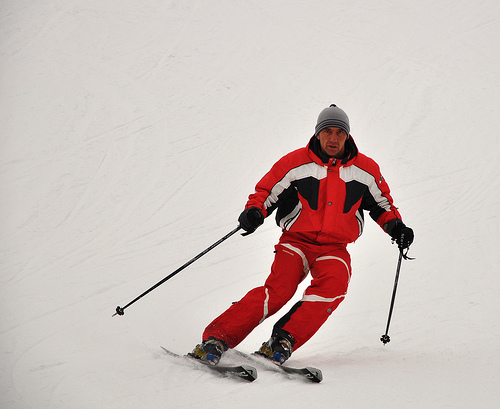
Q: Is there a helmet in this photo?
A: No, there are no helmets.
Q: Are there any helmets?
A: No, there are no helmets.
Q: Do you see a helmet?
A: No, there are no helmets.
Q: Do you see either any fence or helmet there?
A: No, there are no helmets or fences.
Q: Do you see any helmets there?
A: No, there are no helmets.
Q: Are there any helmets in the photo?
A: No, there are no helmets.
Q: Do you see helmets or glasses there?
A: No, there are no helmets or glasses.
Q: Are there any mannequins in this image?
A: No, there are no mannequins.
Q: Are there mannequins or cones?
A: No, there are no mannequins or cones.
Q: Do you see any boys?
A: No, there are no boys.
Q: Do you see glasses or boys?
A: No, there are no boys or glasses.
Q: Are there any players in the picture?
A: No, there are no players.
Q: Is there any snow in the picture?
A: Yes, there is snow.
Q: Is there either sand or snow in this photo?
A: Yes, there is snow.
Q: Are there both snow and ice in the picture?
A: No, there is snow but no ice.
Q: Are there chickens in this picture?
A: No, there are no chickens.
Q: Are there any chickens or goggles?
A: No, there are no chickens or goggles.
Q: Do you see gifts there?
A: No, there are no gifts.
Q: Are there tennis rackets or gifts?
A: No, there are no gifts or tennis rackets.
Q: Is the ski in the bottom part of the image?
A: Yes, the ski is in the bottom of the image.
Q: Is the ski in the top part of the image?
A: No, the ski is in the bottom of the image.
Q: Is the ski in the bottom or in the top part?
A: The ski is in the bottom of the image.